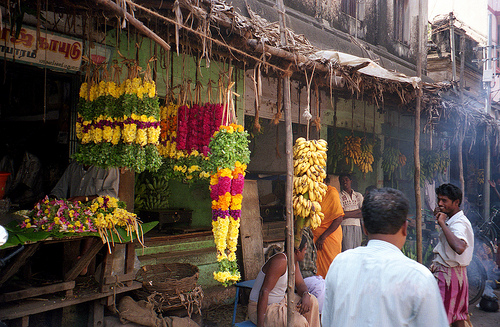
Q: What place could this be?
A: It is a shop.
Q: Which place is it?
A: It is a shop.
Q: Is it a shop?
A: Yes, it is a shop.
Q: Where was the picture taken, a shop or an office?
A: It was taken at a shop.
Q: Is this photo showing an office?
A: No, the picture is showing a shop.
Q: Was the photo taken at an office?
A: No, the picture was taken in a shop.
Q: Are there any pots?
A: Yes, there is a pot.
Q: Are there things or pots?
A: Yes, there is a pot.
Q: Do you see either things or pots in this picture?
A: Yes, there is a pot.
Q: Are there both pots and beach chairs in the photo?
A: No, there is a pot but no beach chairs.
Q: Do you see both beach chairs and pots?
A: No, there is a pot but no beach chairs.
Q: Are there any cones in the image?
A: No, there are no cones.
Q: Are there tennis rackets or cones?
A: No, there are no cones or tennis rackets.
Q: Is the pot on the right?
A: Yes, the pot is on the right of the image.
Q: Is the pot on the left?
A: No, the pot is on the right of the image.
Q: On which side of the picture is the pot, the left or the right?
A: The pot is on the right of the image.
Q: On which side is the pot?
A: The pot is on the right of the image.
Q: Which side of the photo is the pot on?
A: The pot is on the right of the image.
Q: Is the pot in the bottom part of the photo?
A: Yes, the pot is in the bottom of the image.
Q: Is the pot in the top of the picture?
A: No, the pot is in the bottom of the image.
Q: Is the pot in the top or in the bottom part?
A: The pot is in the bottom of the image.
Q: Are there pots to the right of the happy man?
A: Yes, there is a pot to the right of the man.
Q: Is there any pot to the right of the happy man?
A: Yes, there is a pot to the right of the man.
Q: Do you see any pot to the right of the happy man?
A: Yes, there is a pot to the right of the man.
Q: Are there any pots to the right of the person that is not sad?
A: Yes, there is a pot to the right of the man.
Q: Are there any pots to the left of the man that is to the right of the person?
A: No, the pot is to the right of the man.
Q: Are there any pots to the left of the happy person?
A: No, the pot is to the right of the man.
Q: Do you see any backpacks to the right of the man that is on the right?
A: No, there is a pot to the right of the man.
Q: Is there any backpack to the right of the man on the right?
A: No, there is a pot to the right of the man.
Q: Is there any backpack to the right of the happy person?
A: No, there is a pot to the right of the man.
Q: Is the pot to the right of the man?
A: Yes, the pot is to the right of the man.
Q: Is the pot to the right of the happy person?
A: Yes, the pot is to the right of the man.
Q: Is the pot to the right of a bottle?
A: No, the pot is to the right of the man.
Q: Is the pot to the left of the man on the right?
A: No, the pot is to the right of the man.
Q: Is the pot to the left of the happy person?
A: No, the pot is to the right of the man.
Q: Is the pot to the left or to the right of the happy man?
A: The pot is to the right of the man.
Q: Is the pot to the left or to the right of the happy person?
A: The pot is to the right of the man.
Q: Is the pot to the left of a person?
A: No, the pot is to the right of a person.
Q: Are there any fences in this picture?
A: No, there are no fences.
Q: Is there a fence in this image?
A: No, there are no fences.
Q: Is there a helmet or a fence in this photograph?
A: No, there are no fences or helmets.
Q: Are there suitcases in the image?
A: No, there are no suitcases.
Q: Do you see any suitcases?
A: No, there are no suitcases.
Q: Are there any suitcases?
A: No, there are no suitcases.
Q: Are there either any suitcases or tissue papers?
A: No, there are no suitcases or tissue papers.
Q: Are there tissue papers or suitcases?
A: No, there are no suitcases or tissue papers.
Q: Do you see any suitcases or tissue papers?
A: No, there are no suitcases or tissue papers.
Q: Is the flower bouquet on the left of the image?
A: Yes, the bouquet is on the left of the image.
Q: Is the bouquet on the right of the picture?
A: No, the bouquet is on the left of the image.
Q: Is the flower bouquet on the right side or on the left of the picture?
A: The flower bouquet is on the left of the image.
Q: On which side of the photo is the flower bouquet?
A: The flower bouquet is on the left of the image.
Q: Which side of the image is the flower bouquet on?
A: The flower bouquet is on the left of the image.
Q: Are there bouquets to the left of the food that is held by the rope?
A: Yes, there is a bouquet to the left of the food.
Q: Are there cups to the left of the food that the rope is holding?
A: No, there is a bouquet to the left of the food.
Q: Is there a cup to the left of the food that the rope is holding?
A: No, there is a bouquet to the left of the food.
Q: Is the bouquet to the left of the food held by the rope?
A: Yes, the bouquet is to the left of the food.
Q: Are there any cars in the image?
A: No, there are no cars.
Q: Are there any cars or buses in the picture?
A: No, there are no cars or buses.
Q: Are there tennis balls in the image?
A: No, there are no tennis balls.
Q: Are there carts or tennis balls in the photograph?
A: No, there are no tennis balls or carts.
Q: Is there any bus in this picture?
A: No, there are no buses.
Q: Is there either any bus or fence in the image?
A: No, there are no buses or fences.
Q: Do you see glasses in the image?
A: No, there are no glasses.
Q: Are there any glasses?
A: No, there are no glasses.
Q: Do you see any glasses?
A: No, there are no glasses.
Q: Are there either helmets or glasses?
A: No, there are no glasses or helmets.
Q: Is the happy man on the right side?
A: Yes, the man is on the right of the image.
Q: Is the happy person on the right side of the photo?
A: Yes, the man is on the right of the image.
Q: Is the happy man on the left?
A: No, the man is on the right of the image.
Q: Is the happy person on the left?
A: No, the man is on the right of the image.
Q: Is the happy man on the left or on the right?
A: The man is on the right of the image.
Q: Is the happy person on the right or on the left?
A: The man is on the right of the image.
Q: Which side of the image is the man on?
A: The man is on the right of the image.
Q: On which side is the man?
A: The man is on the right of the image.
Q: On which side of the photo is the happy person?
A: The man is on the right of the image.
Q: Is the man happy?
A: Yes, the man is happy.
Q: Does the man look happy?
A: Yes, the man is happy.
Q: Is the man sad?
A: No, the man is happy.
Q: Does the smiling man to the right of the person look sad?
A: No, the man is happy.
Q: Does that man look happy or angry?
A: The man is happy.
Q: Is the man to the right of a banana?
A: Yes, the man is to the right of a banana.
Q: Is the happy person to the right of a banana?
A: Yes, the man is to the right of a banana.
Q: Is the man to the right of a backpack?
A: No, the man is to the right of a banana.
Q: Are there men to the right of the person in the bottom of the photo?
A: Yes, there is a man to the right of the person.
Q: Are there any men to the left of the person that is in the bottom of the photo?
A: No, the man is to the right of the person.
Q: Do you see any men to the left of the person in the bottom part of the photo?
A: No, the man is to the right of the person.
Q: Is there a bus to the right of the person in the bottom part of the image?
A: No, there is a man to the right of the person.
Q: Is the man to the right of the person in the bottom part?
A: Yes, the man is to the right of the person.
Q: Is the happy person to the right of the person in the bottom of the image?
A: Yes, the man is to the right of the person.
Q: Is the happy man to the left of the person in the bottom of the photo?
A: No, the man is to the right of the person.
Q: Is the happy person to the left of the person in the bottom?
A: No, the man is to the right of the person.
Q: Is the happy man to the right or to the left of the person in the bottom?
A: The man is to the right of the person.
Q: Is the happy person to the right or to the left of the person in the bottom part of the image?
A: The man is to the right of the person.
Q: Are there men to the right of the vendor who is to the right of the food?
A: Yes, there is a man to the right of the vendor.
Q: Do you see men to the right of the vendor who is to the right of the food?
A: Yes, there is a man to the right of the vendor.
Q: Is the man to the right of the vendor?
A: Yes, the man is to the right of the vendor.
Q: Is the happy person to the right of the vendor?
A: Yes, the man is to the right of the vendor.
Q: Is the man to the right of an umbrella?
A: No, the man is to the right of the vendor.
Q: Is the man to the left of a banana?
A: No, the man is to the right of a banana.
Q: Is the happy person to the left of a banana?
A: No, the man is to the right of a banana.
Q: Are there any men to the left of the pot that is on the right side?
A: Yes, there is a man to the left of the pot.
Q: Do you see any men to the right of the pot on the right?
A: No, the man is to the left of the pot.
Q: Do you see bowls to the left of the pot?
A: No, there is a man to the left of the pot.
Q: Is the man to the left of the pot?
A: Yes, the man is to the left of the pot.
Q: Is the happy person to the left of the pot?
A: Yes, the man is to the left of the pot.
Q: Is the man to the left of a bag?
A: No, the man is to the left of the pot.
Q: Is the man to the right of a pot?
A: No, the man is to the left of a pot.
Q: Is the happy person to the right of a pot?
A: No, the man is to the left of a pot.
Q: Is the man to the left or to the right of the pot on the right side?
A: The man is to the left of the pot.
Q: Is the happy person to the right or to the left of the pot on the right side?
A: The man is to the left of the pot.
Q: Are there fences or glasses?
A: No, there are no fences or glasses.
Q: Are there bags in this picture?
A: No, there are no bags.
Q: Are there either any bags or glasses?
A: No, there are no bags or glasses.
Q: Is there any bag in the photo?
A: No, there are no bags.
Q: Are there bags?
A: No, there are no bags.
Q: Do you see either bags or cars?
A: No, there are no bags or cars.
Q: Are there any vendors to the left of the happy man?
A: Yes, there is a vendor to the left of the man.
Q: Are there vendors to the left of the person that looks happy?
A: Yes, there is a vendor to the left of the man.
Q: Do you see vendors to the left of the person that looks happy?
A: Yes, there is a vendor to the left of the man.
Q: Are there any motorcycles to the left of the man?
A: No, there is a vendor to the left of the man.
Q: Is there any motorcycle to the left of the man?
A: No, there is a vendor to the left of the man.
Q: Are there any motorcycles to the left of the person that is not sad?
A: No, there is a vendor to the left of the man.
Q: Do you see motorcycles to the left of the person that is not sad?
A: No, there is a vendor to the left of the man.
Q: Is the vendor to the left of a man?
A: Yes, the vendor is to the left of a man.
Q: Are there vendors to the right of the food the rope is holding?
A: Yes, there is a vendor to the right of the food.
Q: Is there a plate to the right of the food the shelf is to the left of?
A: No, there is a vendor to the right of the food.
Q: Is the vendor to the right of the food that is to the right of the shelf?
A: Yes, the vendor is to the right of the food.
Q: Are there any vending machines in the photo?
A: No, there are no vending machines.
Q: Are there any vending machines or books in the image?
A: No, there are no vending machines or books.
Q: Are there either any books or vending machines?
A: No, there are no vending machines or books.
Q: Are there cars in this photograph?
A: No, there are no cars.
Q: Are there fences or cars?
A: No, there are no cars or fences.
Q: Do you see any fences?
A: No, there are no fences.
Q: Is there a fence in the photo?
A: No, there are no fences.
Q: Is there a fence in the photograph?
A: No, there are no fences.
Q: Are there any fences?
A: No, there are no fences.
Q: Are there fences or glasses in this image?
A: No, there are no fences or glasses.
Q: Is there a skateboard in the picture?
A: No, there are no skateboards.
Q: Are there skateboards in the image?
A: No, there are no skateboards.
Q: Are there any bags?
A: No, there are no bags.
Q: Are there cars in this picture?
A: No, there are no cars.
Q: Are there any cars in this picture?
A: No, there are no cars.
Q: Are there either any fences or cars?
A: No, there are no cars or fences.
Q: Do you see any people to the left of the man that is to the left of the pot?
A: Yes, there is a person to the left of the man.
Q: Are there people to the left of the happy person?
A: Yes, there is a person to the left of the man.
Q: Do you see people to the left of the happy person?
A: Yes, there is a person to the left of the man.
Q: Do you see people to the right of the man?
A: No, the person is to the left of the man.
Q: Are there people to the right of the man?
A: No, the person is to the left of the man.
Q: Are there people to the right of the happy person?
A: No, the person is to the left of the man.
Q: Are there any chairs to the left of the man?
A: No, there is a person to the left of the man.